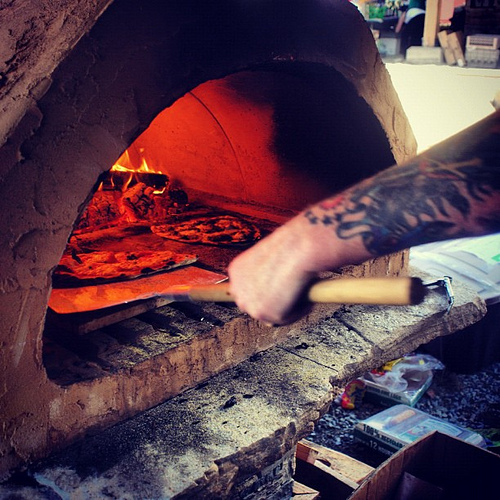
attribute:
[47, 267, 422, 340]
paddle — wooden